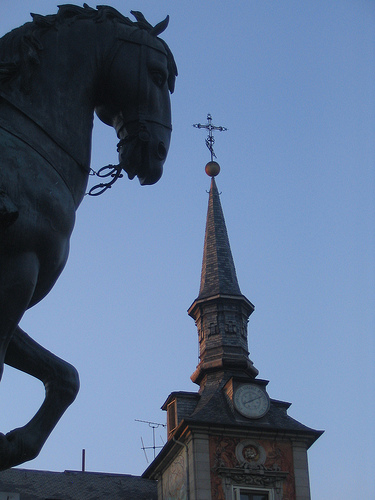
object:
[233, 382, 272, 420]
clock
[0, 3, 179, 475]
horse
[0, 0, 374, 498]
sky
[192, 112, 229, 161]
cross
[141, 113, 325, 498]
building